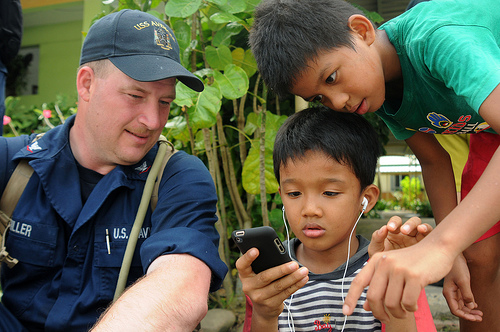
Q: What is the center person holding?
A: A phone.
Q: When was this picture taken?
A: Daytime.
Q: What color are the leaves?
A: Green.